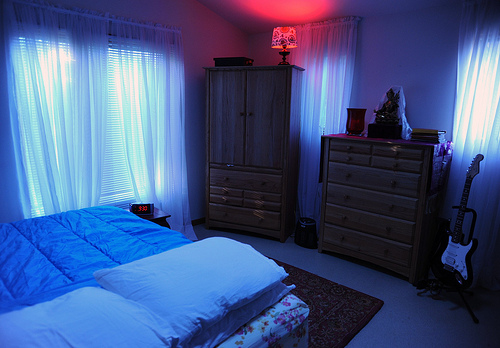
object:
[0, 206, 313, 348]
bed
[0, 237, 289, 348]
pillow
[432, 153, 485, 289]
guitar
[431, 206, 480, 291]
stand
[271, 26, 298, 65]
lamp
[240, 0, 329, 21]
light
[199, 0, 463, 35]
ceiling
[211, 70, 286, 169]
doors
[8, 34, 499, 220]
light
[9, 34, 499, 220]
outside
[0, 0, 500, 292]
blinds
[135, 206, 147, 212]
9:30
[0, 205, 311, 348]
comforter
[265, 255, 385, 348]
carpet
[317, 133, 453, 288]
cabinets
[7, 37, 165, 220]
window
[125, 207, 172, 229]
stool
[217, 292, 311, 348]
flowers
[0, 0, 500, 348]
room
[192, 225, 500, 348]
ground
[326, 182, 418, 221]
drawer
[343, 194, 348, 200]
handle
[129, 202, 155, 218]
alarm clock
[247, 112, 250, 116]
knob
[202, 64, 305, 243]
cabinet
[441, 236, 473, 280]
white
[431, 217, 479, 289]
guitar face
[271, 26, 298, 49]
shade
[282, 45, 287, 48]
lightbulb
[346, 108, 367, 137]
vase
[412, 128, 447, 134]
book